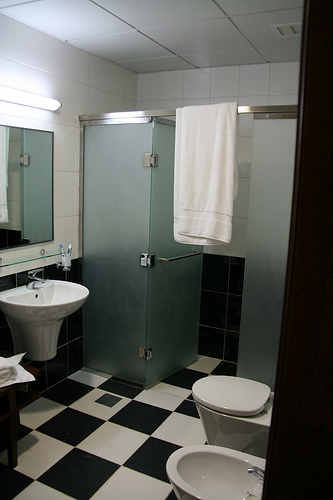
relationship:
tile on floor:
[79, 423, 149, 468] [1, 357, 242, 499]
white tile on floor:
[0, 430, 73, 477] [1, 357, 242, 499]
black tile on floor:
[36, 407, 107, 450] [1, 357, 242, 499]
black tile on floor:
[109, 401, 171, 435] [1, 357, 242, 499]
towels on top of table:
[2, 354, 27, 387] [0, 370, 39, 472]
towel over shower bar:
[171, 105, 238, 250] [79, 103, 298, 115]